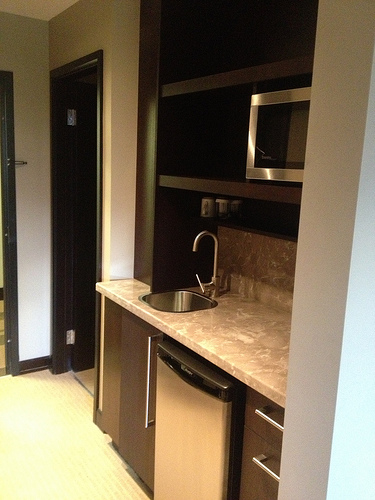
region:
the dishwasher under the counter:
[150, 340, 235, 499]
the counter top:
[95, 277, 293, 405]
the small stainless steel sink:
[140, 288, 216, 314]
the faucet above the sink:
[192, 230, 225, 298]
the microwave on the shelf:
[245, 85, 311, 181]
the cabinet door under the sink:
[115, 305, 161, 491]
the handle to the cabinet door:
[144, 334, 154, 428]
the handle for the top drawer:
[252, 407, 283, 432]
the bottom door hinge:
[66, 329, 75, 344]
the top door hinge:
[67, 108, 76, 125]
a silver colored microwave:
[246, 85, 313, 182]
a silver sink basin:
[142, 289, 215, 312]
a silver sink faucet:
[190, 228, 221, 297]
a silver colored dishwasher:
[152, 337, 234, 498]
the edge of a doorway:
[0, 70, 19, 373]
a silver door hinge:
[65, 329, 74, 342]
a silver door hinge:
[65, 107, 76, 124]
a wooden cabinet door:
[117, 310, 152, 483]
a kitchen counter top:
[94, 274, 289, 403]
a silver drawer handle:
[254, 401, 284, 431]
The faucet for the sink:
[191, 226, 225, 299]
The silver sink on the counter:
[139, 287, 218, 319]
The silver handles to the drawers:
[252, 402, 287, 497]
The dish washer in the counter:
[148, 343, 230, 498]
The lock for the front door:
[7, 156, 30, 171]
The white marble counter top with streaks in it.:
[218, 226, 293, 406]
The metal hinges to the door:
[64, 324, 76, 345]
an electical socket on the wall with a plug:
[194, 194, 217, 220]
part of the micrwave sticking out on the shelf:
[245, 89, 309, 190]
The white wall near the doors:
[13, 62, 55, 357]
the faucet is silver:
[159, 220, 232, 321]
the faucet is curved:
[169, 218, 232, 312]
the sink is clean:
[119, 268, 217, 316]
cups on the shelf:
[169, 190, 278, 244]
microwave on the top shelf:
[224, 84, 337, 179]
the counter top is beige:
[96, 246, 272, 382]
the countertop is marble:
[121, 258, 274, 377]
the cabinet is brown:
[98, 310, 165, 477]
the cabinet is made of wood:
[93, 317, 162, 490]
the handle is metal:
[131, 323, 154, 435]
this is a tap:
[190, 218, 223, 283]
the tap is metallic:
[192, 227, 223, 288]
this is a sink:
[147, 290, 203, 313]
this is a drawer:
[110, 331, 153, 415]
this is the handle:
[139, 338, 151, 422]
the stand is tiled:
[229, 297, 279, 367]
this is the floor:
[19, 394, 87, 485]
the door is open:
[55, 158, 106, 218]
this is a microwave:
[247, 93, 301, 166]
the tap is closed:
[190, 224, 222, 295]